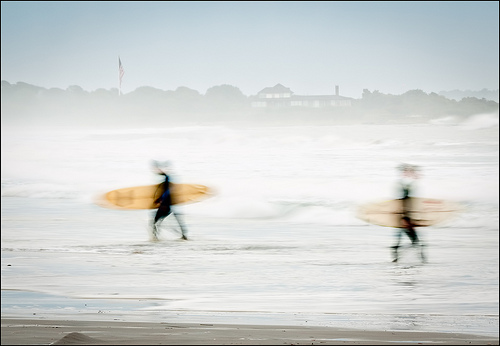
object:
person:
[149, 155, 189, 243]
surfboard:
[95, 182, 221, 211]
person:
[389, 161, 430, 268]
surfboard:
[349, 196, 457, 228]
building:
[246, 81, 353, 118]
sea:
[9, 113, 499, 340]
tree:
[0, 80, 499, 121]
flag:
[119, 61, 125, 81]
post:
[118, 56, 121, 104]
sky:
[1, 0, 500, 102]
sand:
[1, 309, 499, 346]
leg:
[151, 209, 170, 237]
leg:
[174, 210, 190, 233]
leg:
[390, 230, 404, 259]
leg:
[406, 229, 428, 261]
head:
[151, 159, 171, 177]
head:
[398, 165, 419, 182]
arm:
[150, 182, 162, 198]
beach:
[16, 110, 464, 137]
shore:
[2, 278, 499, 344]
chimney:
[335, 85, 340, 96]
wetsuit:
[150, 172, 187, 239]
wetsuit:
[395, 182, 422, 250]